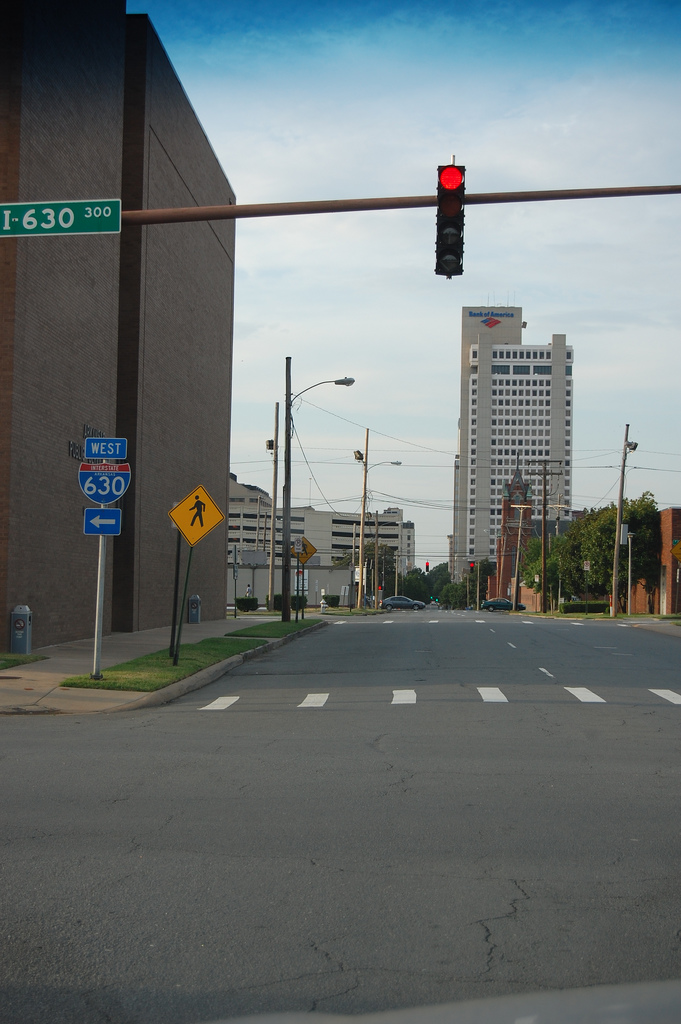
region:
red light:
[425, 139, 477, 282]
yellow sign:
[168, 474, 233, 558]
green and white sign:
[19, 180, 128, 258]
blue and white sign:
[61, 410, 139, 552]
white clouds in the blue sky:
[244, 90, 311, 156]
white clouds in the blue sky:
[274, 249, 326, 310]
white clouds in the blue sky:
[353, 276, 395, 323]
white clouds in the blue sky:
[244, 80, 287, 126]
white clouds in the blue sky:
[531, 77, 579, 126]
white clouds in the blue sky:
[583, 276, 632, 327]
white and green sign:
[9, 188, 120, 263]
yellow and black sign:
[158, 471, 225, 561]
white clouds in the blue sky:
[220, 52, 284, 89]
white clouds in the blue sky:
[287, 282, 357, 334]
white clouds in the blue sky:
[322, 347, 386, 418]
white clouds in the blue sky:
[404, 344, 447, 406]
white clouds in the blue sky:
[503, 192, 567, 282]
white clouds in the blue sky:
[594, 265, 666, 326]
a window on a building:
[489, 373, 497, 388]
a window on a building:
[512, 406, 513, 416]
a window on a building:
[517, 423, 524, 435]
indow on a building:
[524, 435, 526, 442]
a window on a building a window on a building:
[489, 503, 493, 518]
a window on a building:
[531, 381, 543, 383]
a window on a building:
[527, 411, 531, 424]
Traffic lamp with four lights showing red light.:
[432, 158, 462, 276]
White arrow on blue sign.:
[85, 512, 114, 527]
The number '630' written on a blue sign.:
[80, 475, 128, 495]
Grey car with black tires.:
[374, 591, 429, 613]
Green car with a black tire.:
[474, 587, 523, 614]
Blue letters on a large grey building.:
[462, 308, 516, 319]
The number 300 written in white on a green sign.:
[81, 203, 112, 219]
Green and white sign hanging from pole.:
[0, 195, 127, 238]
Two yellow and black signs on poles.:
[168, 481, 318, 674]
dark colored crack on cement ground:
[460, 879, 523, 978]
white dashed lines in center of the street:
[473, 612, 547, 683]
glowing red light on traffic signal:
[424, 145, 474, 294]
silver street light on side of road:
[281, 346, 368, 417]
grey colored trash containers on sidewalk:
[8, 592, 41, 672]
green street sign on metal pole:
[8, 191, 137, 233]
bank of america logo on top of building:
[463, 296, 528, 335]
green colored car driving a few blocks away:
[481, 593, 527, 620]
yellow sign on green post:
[168, 485, 225, 544]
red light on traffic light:
[437, 163, 462, 190]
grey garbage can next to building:
[9, 600, 34, 656]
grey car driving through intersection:
[381, 592, 424, 610]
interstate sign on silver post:
[78, 462, 131, 504]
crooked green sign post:
[173, 545, 194, 670]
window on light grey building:
[494, 362, 514, 374]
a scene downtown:
[63, 308, 669, 781]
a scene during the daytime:
[26, 216, 671, 755]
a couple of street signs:
[40, 405, 231, 703]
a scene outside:
[56, 298, 659, 839]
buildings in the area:
[34, 215, 670, 598]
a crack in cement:
[474, 845, 542, 1004]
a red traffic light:
[414, 150, 493, 314]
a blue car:
[357, 584, 433, 619]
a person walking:
[238, 569, 258, 606]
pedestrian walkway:
[199, 675, 679, 726]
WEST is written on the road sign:
[79, 426, 131, 466]